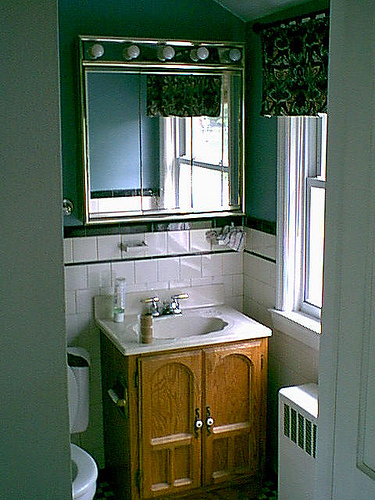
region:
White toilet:
[66, 343, 97, 497]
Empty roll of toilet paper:
[137, 312, 152, 342]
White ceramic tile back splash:
[135, 250, 218, 284]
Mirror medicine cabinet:
[83, 68, 243, 212]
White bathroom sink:
[95, 288, 263, 347]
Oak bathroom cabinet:
[105, 356, 265, 486]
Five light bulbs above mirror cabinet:
[80, 34, 244, 67]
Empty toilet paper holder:
[104, 371, 128, 417]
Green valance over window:
[254, 18, 330, 118]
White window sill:
[267, 297, 321, 345]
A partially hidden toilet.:
[68, 356, 108, 494]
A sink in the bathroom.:
[106, 282, 264, 350]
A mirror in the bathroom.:
[78, 63, 247, 224]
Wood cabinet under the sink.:
[113, 345, 266, 489]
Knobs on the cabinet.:
[191, 405, 217, 435]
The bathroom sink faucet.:
[138, 282, 191, 313]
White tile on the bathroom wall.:
[152, 256, 237, 276]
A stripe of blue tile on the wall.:
[66, 247, 218, 269]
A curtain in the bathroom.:
[250, 13, 330, 115]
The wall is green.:
[9, 68, 53, 241]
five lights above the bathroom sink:
[89, 42, 240, 63]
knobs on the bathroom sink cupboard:
[195, 408, 212, 436]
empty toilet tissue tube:
[142, 313, 150, 341]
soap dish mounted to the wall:
[121, 240, 149, 253]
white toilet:
[70, 366, 91, 493]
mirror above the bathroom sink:
[88, 70, 238, 214]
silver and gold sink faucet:
[148, 293, 183, 312]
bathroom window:
[298, 118, 318, 326]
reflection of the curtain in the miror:
[151, 77, 222, 117]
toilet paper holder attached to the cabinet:
[109, 379, 127, 411]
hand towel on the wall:
[201, 216, 266, 270]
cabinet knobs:
[170, 392, 253, 471]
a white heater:
[245, 356, 358, 497]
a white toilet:
[52, 331, 110, 497]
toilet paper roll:
[123, 293, 174, 387]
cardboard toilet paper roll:
[120, 312, 173, 359]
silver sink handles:
[133, 279, 225, 349]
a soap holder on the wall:
[113, 233, 176, 275]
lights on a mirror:
[50, 22, 256, 226]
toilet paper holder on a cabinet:
[78, 366, 146, 423]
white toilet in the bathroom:
[66, 214, 258, 319]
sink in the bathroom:
[95, 280, 266, 490]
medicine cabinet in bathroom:
[60, 20, 241, 222]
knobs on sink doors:
[185, 412, 217, 427]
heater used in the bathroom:
[270, 376, 320, 490]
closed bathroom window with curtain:
[263, 85, 323, 343]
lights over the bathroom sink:
[67, 22, 238, 58]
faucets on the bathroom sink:
[137, 286, 190, 311]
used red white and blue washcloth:
[198, 220, 243, 251]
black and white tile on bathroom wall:
[58, 217, 260, 302]